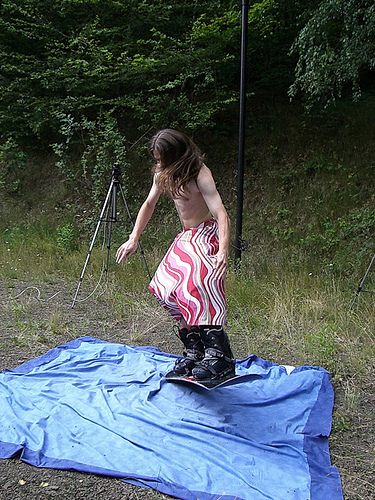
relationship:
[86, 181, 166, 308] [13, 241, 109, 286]
tripod in grass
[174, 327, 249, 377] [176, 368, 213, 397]
boots on snowboard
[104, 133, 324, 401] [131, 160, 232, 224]
man without shirt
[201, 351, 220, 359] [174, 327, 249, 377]
buckles on boots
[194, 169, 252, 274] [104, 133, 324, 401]
arm of man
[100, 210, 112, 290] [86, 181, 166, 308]
wire hanging from tripod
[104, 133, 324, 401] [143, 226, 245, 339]
man wearing skirt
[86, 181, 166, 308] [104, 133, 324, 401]
tripod left of man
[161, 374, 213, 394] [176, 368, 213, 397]
nose of snowboard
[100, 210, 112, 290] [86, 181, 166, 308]
wire for tripod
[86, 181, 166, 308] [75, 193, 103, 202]
tripod in back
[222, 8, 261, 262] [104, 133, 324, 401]
pole behind man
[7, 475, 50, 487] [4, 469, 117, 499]
stones on ground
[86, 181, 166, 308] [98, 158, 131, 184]
tripod for camera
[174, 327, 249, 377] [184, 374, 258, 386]
boots for snow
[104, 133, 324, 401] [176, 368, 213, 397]
man on snowboard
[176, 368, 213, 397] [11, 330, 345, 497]
snowboard on blanket